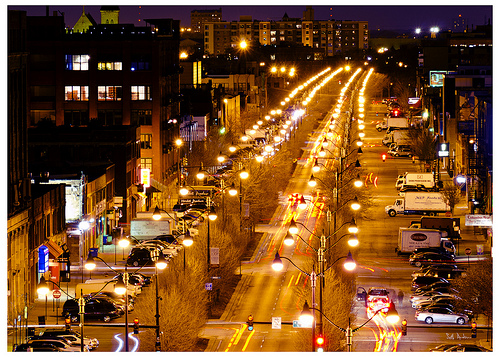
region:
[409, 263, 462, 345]
A car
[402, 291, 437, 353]
A car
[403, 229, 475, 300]
A car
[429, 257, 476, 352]
A car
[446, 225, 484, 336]
A car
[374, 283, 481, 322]
A car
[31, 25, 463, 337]
A city scene at night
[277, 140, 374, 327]
A row of street lights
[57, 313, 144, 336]
These are traffic lights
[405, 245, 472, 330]
Cars are parked here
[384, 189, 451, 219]
A box truck is parked here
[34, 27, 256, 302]
Buildings line the street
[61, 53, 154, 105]
The lights are on in this building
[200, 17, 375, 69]
A large building is in the distance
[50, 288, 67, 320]
A Do Not Enter sign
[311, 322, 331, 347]
This traffic light is red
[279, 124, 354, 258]
The streetlights are visible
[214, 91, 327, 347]
The streetlights are visible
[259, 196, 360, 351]
The streetlights are visible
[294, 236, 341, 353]
The streetlights are visible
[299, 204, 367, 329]
The streetlights are visible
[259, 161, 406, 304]
The streetlights are visible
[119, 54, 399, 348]
row of streetlamps through city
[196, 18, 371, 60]
large lit up building in distance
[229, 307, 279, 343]
green traffic light on pole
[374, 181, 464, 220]
white delivery box truck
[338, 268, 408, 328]
red car stopped in front of building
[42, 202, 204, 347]
cars parked down the street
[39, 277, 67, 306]
round red stop sign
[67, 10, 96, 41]
building shaped like a pyramid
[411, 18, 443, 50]
powerful lamps in the distance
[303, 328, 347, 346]
red traffic stop light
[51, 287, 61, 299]
DO NOT ENTER SIGN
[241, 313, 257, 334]
GREEN TRAFFIC LIGHT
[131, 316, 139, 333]
RED TRAFFIC LIGHT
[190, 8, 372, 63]
APARTMENT BUILDINGS IN THE BACKGROUND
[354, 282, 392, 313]
CAR WITH THE DRIVER'S DOOR OPEN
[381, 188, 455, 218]
PARKED DELIVERY TRUCK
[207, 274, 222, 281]
BLUE STREET SIGN WITH WHITE LETTERS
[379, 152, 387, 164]
RED STOP LIGHT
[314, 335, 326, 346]
RED STOP LIGHT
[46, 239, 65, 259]
AWNING ON THE BUILDING